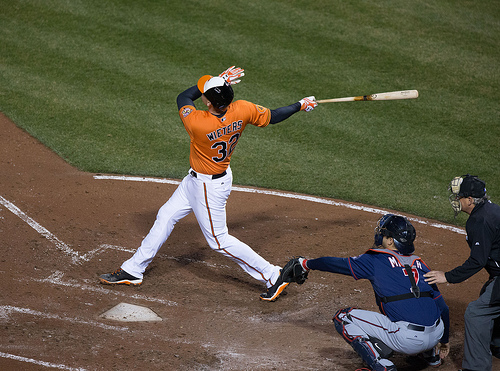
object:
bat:
[319, 90, 419, 101]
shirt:
[177, 83, 301, 176]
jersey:
[177, 100, 272, 175]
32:
[212, 133, 239, 163]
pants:
[119, 168, 283, 287]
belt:
[189, 167, 233, 181]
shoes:
[100, 268, 147, 287]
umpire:
[424, 174, 499, 371]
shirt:
[445, 199, 500, 287]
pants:
[461, 277, 499, 371]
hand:
[300, 95, 317, 113]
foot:
[100, 267, 144, 286]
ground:
[0, 0, 499, 370]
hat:
[195, 73, 233, 108]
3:
[212, 140, 225, 163]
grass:
[0, 0, 499, 231]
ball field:
[0, 109, 499, 371]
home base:
[101, 302, 161, 324]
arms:
[259, 103, 299, 127]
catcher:
[278, 214, 451, 371]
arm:
[298, 254, 371, 280]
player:
[279, 213, 451, 371]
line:
[93, 173, 466, 238]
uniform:
[127, 79, 300, 285]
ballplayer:
[99, 64, 317, 304]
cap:
[197, 73, 232, 110]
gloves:
[298, 95, 318, 115]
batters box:
[49, 243, 319, 329]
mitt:
[279, 257, 310, 284]